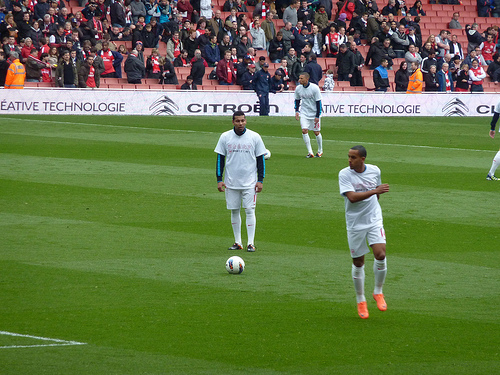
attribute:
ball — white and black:
[226, 253, 246, 272]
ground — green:
[1, 114, 497, 373]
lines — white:
[1, 327, 85, 350]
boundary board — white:
[1, 86, 498, 116]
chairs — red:
[1, 0, 498, 89]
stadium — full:
[1, 1, 498, 372]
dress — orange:
[4, 61, 26, 86]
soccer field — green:
[1, 111, 498, 372]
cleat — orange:
[349, 292, 370, 321]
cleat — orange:
[369, 283, 389, 308]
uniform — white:
[333, 164, 391, 234]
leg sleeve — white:
[224, 205, 243, 245]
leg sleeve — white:
[241, 205, 260, 245]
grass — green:
[53, 229, 168, 336]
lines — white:
[10, 313, 80, 373]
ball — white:
[221, 243, 251, 280]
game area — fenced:
[17, 87, 488, 357]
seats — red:
[118, 70, 164, 94]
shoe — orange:
[352, 290, 374, 320]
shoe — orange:
[372, 286, 391, 314]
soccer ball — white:
[222, 243, 249, 281]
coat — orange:
[2, 60, 31, 89]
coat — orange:
[407, 71, 428, 94]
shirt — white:
[338, 163, 385, 209]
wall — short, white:
[20, 87, 482, 117]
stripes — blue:
[213, 150, 230, 180]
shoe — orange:
[347, 291, 371, 321]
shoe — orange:
[368, 284, 395, 311]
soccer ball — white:
[222, 249, 249, 279]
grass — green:
[14, 122, 291, 332]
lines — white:
[3, 324, 90, 360]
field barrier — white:
[4, 87, 480, 122]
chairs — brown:
[415, 3, 475, 52]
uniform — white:
[218, 129, 259, 240]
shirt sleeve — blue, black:
[254, 150, 269, 185]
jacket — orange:
[402, 65, 426, 95]